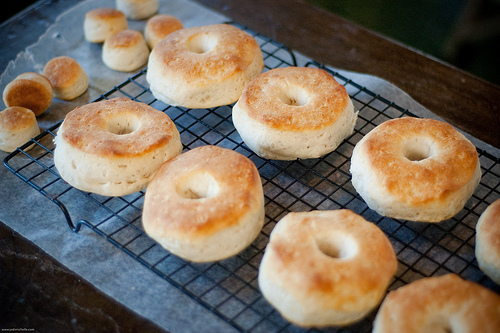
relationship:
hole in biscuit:
[187, 33, 216, 54] [146, 24, 263, 109]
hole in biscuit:
[280, 85, 309, 109] [232, 66, 360, 160]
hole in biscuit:
[399, 136, 434, 162] [350, 116, 483, 223]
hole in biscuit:
[103, 112, 142, 136] [52, 96, 183, 196]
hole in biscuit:
[175, 170, 218, 203] [142, 146, 265, 264]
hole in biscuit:
[314, 228, 359, 259] [258, 208, 398, 328]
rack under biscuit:
[3, 22, 499, 332] [146, 24, 263, 109]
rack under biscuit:
[3, 22, 499, 332] [232, 66, 360, 160]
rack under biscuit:
[3, 22, 499, 332] [350, 116, 483, 223]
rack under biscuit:
[3, 22, 499, 332] [52, 96, 183, 196]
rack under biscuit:
[3, 22, 499, 332] [142, 146, 265, 264]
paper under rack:
[0, 0, 499, 332] [3, 22, 499, 332]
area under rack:
[8, 49, 498, 331] [3, 22, 499, 332]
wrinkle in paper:
[64, 69, 399, 257] [0, 0, 499, 332]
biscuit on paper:
[146, 24, 263, 109] [0, 0, 499, 332]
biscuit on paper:
[232, 66, 360, 160] [0, 0, 499, 332]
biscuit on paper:
[350, 116, 483, 223] [0, 0, 499, 332]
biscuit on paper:
[52, 96, 183, 196] [0, 0, 499, 332]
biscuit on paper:
[142, 146, 265, 264] [0, 0, 499, 332]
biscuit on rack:
[146, 24, 263, 109] [3, 22, 499, 332]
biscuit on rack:
[232, 66, 360, 160] [3, 22, 499, 332]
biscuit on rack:
[350, 116, 483, 223] [3, 22, 499, 332]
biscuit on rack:
[52, 96, 183, 196] [3, 22, 499, 332]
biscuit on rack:
[142, 146, 265, 264] [3, 22, 499, 332]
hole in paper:
[54, 31, 64, 41] [0, 0, 499, 332]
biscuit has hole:
[146, 24, 263, 109] [187, 33, 216, 54]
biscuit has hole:
[232, 66, 360, 160] [280, 85, 309, 109]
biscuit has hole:
[350, 116, 483, 223] [399, 136, 434, 162]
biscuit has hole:
[52, 96, 183, 196] [103, 112, 142, 136]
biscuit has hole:
[142, 146, 265, 264] [175, 170, 218, 203]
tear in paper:
[20, 45, 47, 73] [0, 0, 499, 332]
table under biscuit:
[1, 0, 498, 332] [146, 24, 263, 109]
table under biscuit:
[1, 0, 498, 332] [232, 66, 360, 160]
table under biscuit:
[1, 0, 498, 332] [350, 116, 483, 223]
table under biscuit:
[1, 0, 498, 332] [52, 96, 183, 196]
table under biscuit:
[1, 0, 498, 332] [142, 146, 265, 264]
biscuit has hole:
[258, 208, 398, 328] [314, 228, 359, 259]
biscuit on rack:
[258, 208, 398, 328] [3, 22, 499, 332]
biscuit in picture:
[146, 24, 263, 109] [1, 0, 499, 332]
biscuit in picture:
[232, 66, 360, 160] [1, 0, 499, 332]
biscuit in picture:
[350, 116, 483, 223] [1, 0, 499, 332]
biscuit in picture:
[258, 208, 398, 328] [1, 0, 499, 332]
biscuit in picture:
[142, 146, 265, 264] [1, 0, 499, 332]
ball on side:
[1, 105, 41, 154] [0, 0, 236, 164]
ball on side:
[3, 71, 53, 117] [0, 0, 236, 164]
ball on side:
[44, 56, 89, 101] [0, 0, 236, 164]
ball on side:
[102, 28, 152, 72] [0, 0, 236, 164]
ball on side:
[83, 8, 127, 44] [0, 0, 236, 164]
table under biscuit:
[1, 0, 498, 332] [258, 208, 398, 328]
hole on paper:
[187, 33, 216, 54] [0, 0, 499, 332]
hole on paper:
[399, 136, 434, 162] [0, 0, 499, 332]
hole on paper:
[314, 228, 359, 259] [0, 0, 499, 332]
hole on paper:
[175, 170, 218, 203] [0, 0, 499, 332]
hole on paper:
[103, 112, 142, 136] [0, 0, 499, 332]